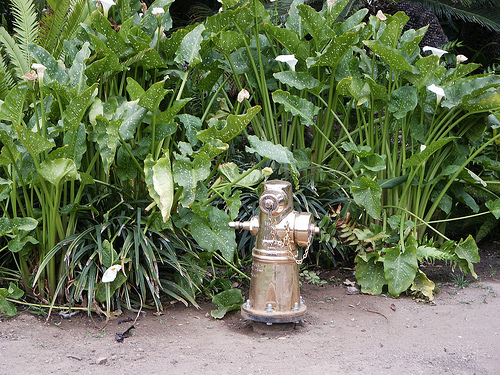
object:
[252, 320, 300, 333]
bottom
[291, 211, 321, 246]
side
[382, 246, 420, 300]
leaves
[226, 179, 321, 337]
fire hydrant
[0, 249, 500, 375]
dirt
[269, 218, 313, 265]
chain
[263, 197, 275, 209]
nut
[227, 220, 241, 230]
nut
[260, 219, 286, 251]
stamp